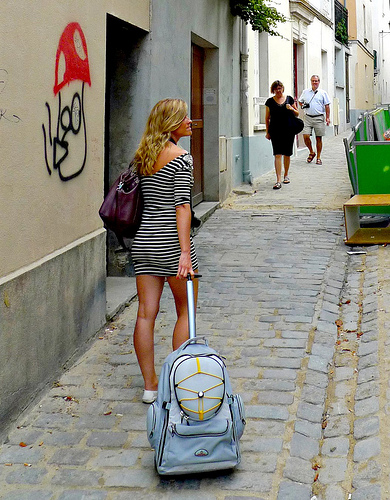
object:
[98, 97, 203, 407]
woman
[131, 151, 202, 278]
dress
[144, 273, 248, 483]
luggage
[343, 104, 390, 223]
bin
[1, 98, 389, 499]
alley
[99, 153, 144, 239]
purse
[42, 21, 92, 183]
graffiti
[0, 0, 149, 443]
wall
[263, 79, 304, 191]
woman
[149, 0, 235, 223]
building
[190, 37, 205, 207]
entrance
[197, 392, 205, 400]
latch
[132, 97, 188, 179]
hair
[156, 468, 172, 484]
wheels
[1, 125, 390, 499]
sidewalk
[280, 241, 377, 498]
gutter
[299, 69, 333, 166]
pedestrian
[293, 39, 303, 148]
doorway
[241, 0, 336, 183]
building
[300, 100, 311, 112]
camera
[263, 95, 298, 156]
dress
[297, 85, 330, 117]
shirt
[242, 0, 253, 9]
leaves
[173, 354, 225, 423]
cording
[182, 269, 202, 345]
handle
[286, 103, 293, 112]
hand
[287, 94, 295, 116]
strap